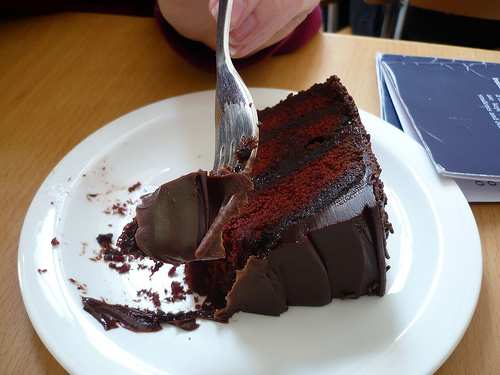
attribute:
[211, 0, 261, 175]
fork — large, silver, metal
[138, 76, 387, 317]
cake — chocolate, cut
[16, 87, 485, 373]
plate — white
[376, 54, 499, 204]
book — old, blue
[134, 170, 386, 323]
frosting — chocolate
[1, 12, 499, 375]
table — wood, wooden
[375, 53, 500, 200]
books — blue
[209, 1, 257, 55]
nails — unpolished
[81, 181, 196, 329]
frosting — smeared